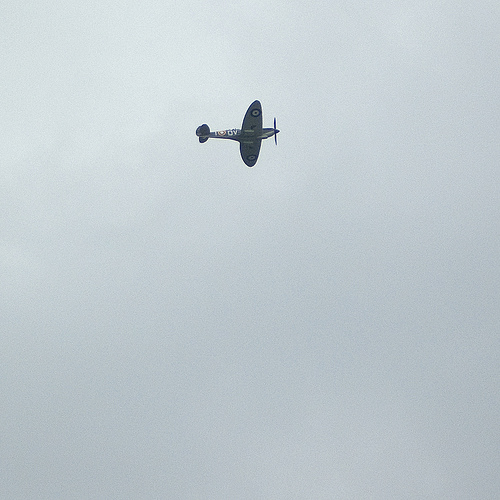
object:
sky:
[0, 0, 500, 497]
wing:
[242, 110, 263, 128]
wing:
[239, 142, 261, 167]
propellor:
[273, 117, 280, 146]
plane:
[195, 100, 280, 168]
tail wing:
[195, 123, 209, 143]